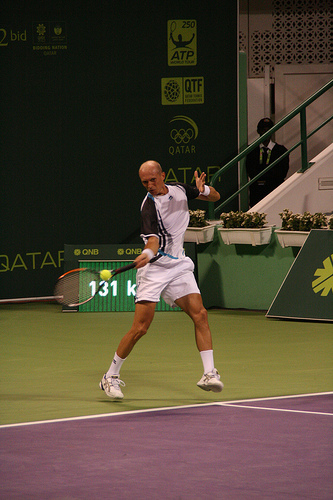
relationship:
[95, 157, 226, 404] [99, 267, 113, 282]
man hitting a tennis ball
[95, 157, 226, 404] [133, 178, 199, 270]
man wearing a shirt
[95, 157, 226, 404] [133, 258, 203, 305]
man wearing shorts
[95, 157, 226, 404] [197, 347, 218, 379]
man wearing sock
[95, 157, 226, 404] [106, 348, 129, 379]
man wearing sock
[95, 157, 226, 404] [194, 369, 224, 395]
man wearing tennis shoe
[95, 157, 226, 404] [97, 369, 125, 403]
man wearing tennis shoe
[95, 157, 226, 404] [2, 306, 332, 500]
man off of ground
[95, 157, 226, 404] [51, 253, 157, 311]
man swinging a racquet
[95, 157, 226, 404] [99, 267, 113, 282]
man hitting tennis ball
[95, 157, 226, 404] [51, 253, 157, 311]
man has a racquet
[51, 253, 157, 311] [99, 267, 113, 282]
racquet hitting a tennis ball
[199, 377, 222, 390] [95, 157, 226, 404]
foot of a man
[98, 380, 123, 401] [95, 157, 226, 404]
foot of a man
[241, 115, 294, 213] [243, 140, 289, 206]
man in a suit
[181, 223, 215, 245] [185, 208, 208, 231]
planter has flowers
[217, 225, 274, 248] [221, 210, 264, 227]
planter has flowers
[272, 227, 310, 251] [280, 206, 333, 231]
planter has flowers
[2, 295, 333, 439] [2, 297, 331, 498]
section of tennis court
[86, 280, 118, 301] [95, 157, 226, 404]
number behind man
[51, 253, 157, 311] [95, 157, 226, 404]
racquet held by man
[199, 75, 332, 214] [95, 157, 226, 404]
railing behind man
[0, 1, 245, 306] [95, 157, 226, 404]
wall behind man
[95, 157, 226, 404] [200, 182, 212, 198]
man wearing a wrist band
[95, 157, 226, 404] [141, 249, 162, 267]
man wearing a wrist band